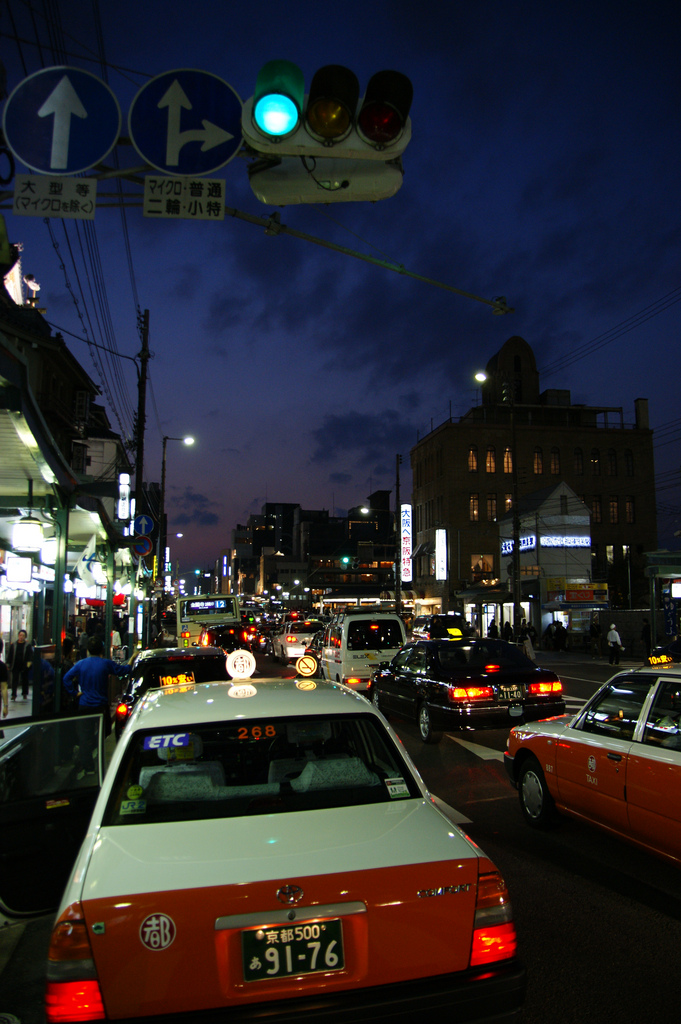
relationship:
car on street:
[0, 648, 515, 1021] [0, 596, 680, 1023]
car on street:
[505, 664, 680, 858] [0, 596, 680, 1023]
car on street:
[367, 637, 568, 741] [0, 596, 680, 1023]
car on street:
[366, 627, 566, 744] [0, 596, 680, 1023]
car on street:
[315, 611, 410, 687] [0, 596, 680, 1023]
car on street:
[245, 619, 280, 651] [0, 596, 680, 1023]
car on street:
[191, 622, 251, 654] [0, 596, 680, 1023]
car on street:
[267, 618, 325, 660] [0, 596, 680, 1023]